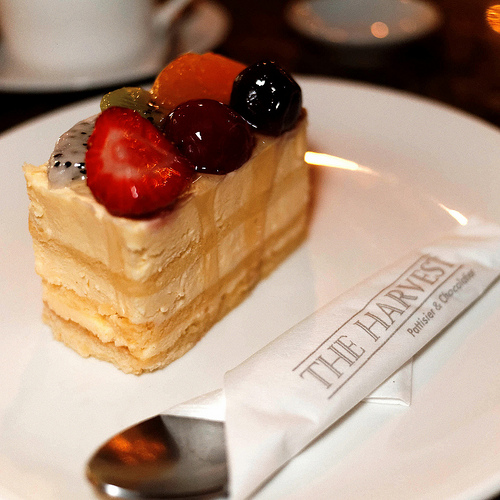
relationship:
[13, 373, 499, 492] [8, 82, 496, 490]
dessert on plate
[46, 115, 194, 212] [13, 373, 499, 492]
strawberries are on top of dessert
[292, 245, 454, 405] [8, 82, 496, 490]
harvest name of restaurant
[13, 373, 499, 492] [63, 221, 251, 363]
dessert made from ice cream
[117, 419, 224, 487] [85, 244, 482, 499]
bowl of spoon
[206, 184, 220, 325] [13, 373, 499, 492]
fruit juices are running down dessert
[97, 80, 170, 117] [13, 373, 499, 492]
kiwi on dessert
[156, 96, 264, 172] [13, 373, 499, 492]
cherry on dessert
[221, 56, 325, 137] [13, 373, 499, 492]
blueberry on dessert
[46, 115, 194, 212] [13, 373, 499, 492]
strawberries are on dessert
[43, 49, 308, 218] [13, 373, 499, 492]
mixed fruit on dessert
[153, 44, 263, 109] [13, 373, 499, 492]
orange on dessert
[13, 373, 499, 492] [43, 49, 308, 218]
dessert has mixed fruit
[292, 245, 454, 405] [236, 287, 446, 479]
harvest on napkin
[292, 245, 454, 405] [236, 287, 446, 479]
harvest logo on napkin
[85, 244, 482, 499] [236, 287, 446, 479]
spoon wrapped in napkin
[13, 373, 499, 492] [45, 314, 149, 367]
dessert in layers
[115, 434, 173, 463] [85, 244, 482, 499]
reflection from spoon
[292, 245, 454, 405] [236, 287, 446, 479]
harvest written on napkin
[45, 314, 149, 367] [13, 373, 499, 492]
layers are on dessert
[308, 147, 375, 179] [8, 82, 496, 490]
light on plate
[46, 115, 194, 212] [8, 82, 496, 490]
strawberries are on plate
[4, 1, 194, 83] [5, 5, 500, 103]
coffee mug in background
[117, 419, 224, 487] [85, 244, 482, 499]
bowl from spoon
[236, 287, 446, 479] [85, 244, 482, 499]
napkin wrapped around spoon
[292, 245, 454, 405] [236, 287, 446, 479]
harvest printed on napkin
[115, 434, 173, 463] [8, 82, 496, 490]
reflection on plate